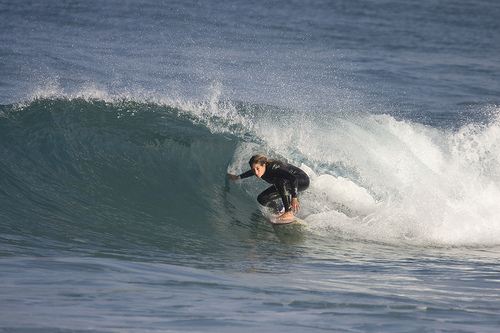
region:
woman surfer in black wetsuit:
[225, 153, 311, 228]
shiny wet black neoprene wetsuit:
[238, 162, 310, 209]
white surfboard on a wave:
[261, 209, 307, 227]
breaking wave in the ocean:
[1, 87, 497, 237]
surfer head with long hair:
[250, 153, 271, 178]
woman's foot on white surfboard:
[273, 208, 295, 221]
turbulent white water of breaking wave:
[297, 114, 499, 242]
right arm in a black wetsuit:
[227, 169, 252, 180]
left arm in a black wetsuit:
[269, 167, 301, 213]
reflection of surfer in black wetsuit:
[214, 178, 264, 270]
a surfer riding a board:
[231, 143, 312, 237]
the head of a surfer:
[250, 155, 270, 180]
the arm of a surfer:
[214, 163, 251, 185]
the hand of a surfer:
[214, 169, 232, 183]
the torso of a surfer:
[270, 159, 312, 187]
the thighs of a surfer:
[258, 173, 286, 194]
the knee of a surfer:
[245, 193, 266, 203]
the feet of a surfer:
[262, 202, 290, 222]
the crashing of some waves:
[348, 165, 422, 226]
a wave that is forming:
[32, 68, 176, 208]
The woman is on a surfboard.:
[222, 137, 316, 234]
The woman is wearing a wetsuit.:
[196, 115, 336, 250]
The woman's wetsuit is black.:
[213, 134, 324, 244]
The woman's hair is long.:
[222, 146, 315, 236]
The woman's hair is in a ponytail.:
[209, 147, 326, 247]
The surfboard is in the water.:
[199, 115, 346, 248]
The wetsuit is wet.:
[201, 141, 350, 258]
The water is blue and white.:
[2, 2, 499, 332]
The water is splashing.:
[3, 3, 499, 331]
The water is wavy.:
[0, 1, 498, 331]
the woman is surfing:
[227, 152, 315, 229]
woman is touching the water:
[217, 141, 315, 228]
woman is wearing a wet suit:
[226, 149, 311, 230]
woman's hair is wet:
[248, 149, 279, 166]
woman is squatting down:
[224, 148, 314, 223]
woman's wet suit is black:
[227, 148, 312, 225]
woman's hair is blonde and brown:
[245, 154, 281, 167]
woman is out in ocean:
[224, 154, 308, 224]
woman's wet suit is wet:
[236, 153, 318, 223]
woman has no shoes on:
[268, 199, 298, 227]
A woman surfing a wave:
[218, 142, 324, 237]